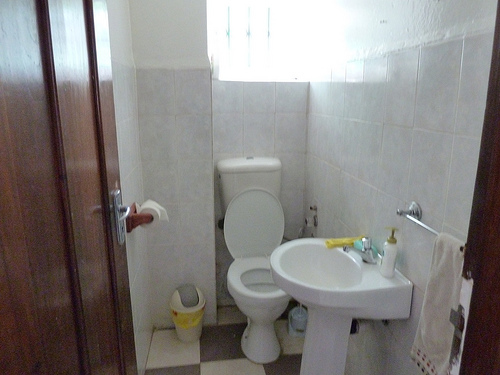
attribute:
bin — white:
[148, 287, 230, 351]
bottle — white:
[387, 160, 417, 285]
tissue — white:
[87, 182, 207, 278]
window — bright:
[171, 9, 311, 70]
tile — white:
[199, 353, 242, 369]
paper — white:
[119, 180, 174, 247]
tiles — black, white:
[123, 314, 321, 372]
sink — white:
[259, 220, 411, 360]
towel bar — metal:
[395, 200, 438, 238]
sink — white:
[271, 232, 410, 320]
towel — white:
[408, 235, 469, 370]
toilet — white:
[156, 162, 398, 365]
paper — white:
[96, 144, 225, 268]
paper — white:
[108, 148, 224, 297]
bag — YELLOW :
[172, 308, 202, 328]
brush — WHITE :
[286, 296, 313, 335]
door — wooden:
[3, 4, 145, 371]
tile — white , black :
[201, 317, 256, 361]